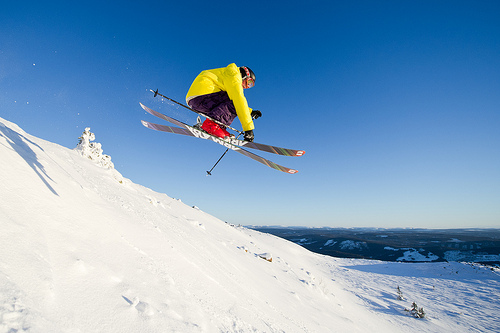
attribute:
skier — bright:
[131, 40, 326, 192]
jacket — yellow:
[184, 41, 267, 141]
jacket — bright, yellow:
[178, 47, 276, 138]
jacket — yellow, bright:
[184, 45, 262, 134]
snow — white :
[4, 118, 498, 317]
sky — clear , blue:
[6, 9, 493, 287]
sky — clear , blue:
[1, 3, 498, 231]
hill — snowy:
[332, 232, 375, 259]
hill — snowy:
[437, 229, 463, 267]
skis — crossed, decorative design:
[134, 99, 310, 183]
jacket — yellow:
[188, 62, 257, 125]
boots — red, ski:
[193, 112, 236, 139]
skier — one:
[186, 55, 258, 150]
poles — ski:
[210, 81, 253, 177]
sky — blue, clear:
[38, 10, 208, 53]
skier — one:
[196, 60, 266, 144]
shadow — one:
[5, 111, 75, 209]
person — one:
[186, 51, 265, 133]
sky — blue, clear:
[19, 14, 463, 59]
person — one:
[188, 57, 267, 134]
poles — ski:
[194, 99, 262, 174]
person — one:
[185, 49, 267, 153]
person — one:
[189, 55, 268, 157]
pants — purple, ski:
[191, 96, 242, 136]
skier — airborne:
[191, 49, 259, 171]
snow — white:
[120, 210, 202, 259]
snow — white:
[101, 249, 233, 332]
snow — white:
[339, 298, 371, 329]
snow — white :
[1, 116, 484, 331]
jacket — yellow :
[188, 59, 254, 128]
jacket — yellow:
[178, 53, 268, 133]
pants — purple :
[192, 90, 242, 135]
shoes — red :
[194, 114, 234, 142]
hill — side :
[0, 108, 293, 330]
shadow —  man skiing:
[6, 117, 57, 197]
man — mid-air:
[133, 34, 310, 188]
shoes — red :
[198, 110, 231, 146]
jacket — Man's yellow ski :
[185, 57, 262, 141]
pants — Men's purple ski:
[191, 91, 237, 130]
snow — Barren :
[249, 254, 324, 306]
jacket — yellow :
[180, 58, 263, 133]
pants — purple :
[186, 91, 236, 128]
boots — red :
[196, 114, 233, 143]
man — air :
[172, 47, 265, 146]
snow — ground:
[4, 127, 461, 327]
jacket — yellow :
[175, 58, 270, 136]